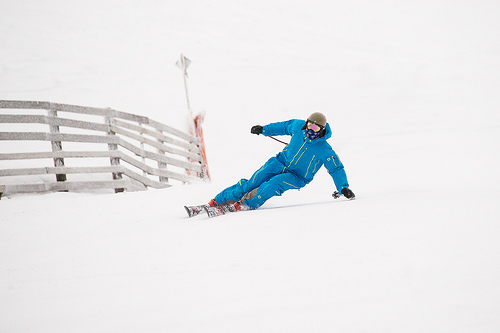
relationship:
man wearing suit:
[247, 92, 368, 213] [251, 124, 323, 201]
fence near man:
[55, 102, 147, 191] [247, 92, 368, 213]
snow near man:
[122, 211, 201, 255] [247, 92, 368, 213]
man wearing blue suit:
[247, 92, 368, 213] [251, 124, 323, 201]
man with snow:
[247, 92, 368, 213] [122, 211, 201, 255]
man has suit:
[247, 92, 368, 213] [251, 124, 323, 201]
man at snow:
[247, 92, 368, 213] [122, 211, 201, 255]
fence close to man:
[55, 102, 147, 191] [247, 92, 368, 213]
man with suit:
[247, 92, 368, 213] [251, 124, 323, 201]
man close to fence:
[247, 92, 368, 213] [55, 102, 147, 191]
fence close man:
[55, 102, 147, 191] [247, 92, 368, 213]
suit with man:
[251, 124, 323, 201] [247, 92, 368, 213]